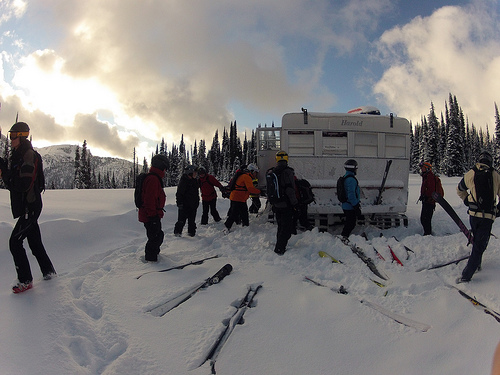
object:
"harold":
[341, 120, 363, 127]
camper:
[0, 122, 500, 295]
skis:
[136, 255, 262, 374]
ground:
[0, 173, 500, 375]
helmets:
[275, 150, 289, 163]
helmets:
[344, 159, 358, 176]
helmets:
[418, 162, 432, 172]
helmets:
[476, 151, 493, 168]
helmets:
[247, 163, 260, 175]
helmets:
[197, 166, 206, 178]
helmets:
[182, 165, 198, 179]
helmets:
[151, 154, 170, 171]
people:
[134, 154, 170, 261]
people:
[174, 166, 200, 238]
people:
[197, 166, 224, 225]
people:
[222, 163, 263, 230]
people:
[267, 149, 297, 254]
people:
[336, 159, 361, 239]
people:
[416, 162, 444, 236]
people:
[456, 151, 500, 284]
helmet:
[8, 121, 30, 140]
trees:
[0, 92, 499, 189]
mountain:
[33, 144, 151, 189]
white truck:
[255, 106, 411, 232]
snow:
[0, 174, 500, 375]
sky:
[0, 0, 499, 170]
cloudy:
[15, 0, 241, 151]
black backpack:
[474, 166, 494, 212]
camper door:
[253, 127, 282, 193]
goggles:
[10, 134, 18, 141]